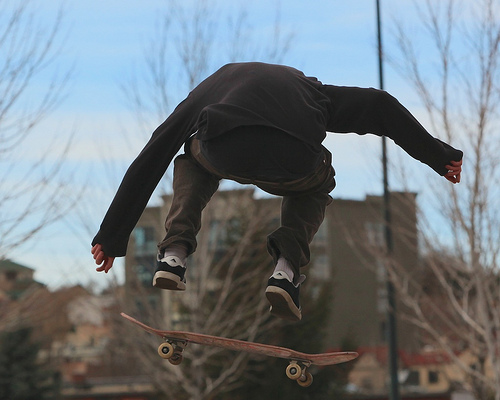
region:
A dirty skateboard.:
[118, 311, 360, 384]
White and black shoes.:
[150, 255, 308, 322]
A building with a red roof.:
[358, 341, 451, 397]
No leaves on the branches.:
[364, 213, 499, 334]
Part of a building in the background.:
[337, 190, 417, 334]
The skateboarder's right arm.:
[331, 82, 465, 182]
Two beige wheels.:
[155, 343, 186, 365]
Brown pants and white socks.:
[159, 158, 336, 275]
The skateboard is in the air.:
[119, 310, 360, 386]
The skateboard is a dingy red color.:
[119, 312, 357, 387]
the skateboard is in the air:
[107, 297, 352, 391]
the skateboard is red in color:
[101, 310, 393, 376]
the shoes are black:
[145, 253, 332, 325]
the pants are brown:
[161, 179, 332, 256]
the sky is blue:
[62, 13, 470, 63]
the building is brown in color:
[122, 206, 429, 331]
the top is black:
[173, 67, 422, 129]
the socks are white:
[156, 243, 303, 282]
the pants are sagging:
[169, 121, 360, 211]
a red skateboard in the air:
[120, 303, 357, 386]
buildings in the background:
[9, 195, 496, 398]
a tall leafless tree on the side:
[368, 10, 498, 398]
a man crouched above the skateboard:
[92, 62, 464, 299]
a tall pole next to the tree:
[366, 2, 428, 397]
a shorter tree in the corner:
[8, 322, 75, 398]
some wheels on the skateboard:
[280, 362, 313, 385]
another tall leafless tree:
[1, 0, 84, 271]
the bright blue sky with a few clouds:
[6, 3, 497, 93]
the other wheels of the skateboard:
[149, 338, 184, 363]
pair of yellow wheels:
[152, 341, 186, 368]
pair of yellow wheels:
[282, 364, 319, 387]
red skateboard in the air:
[110, 302, 372, 399]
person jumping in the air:
[69, 20, 476, 398]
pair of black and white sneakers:
[147, 252, 317, 324]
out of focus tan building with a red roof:
[335, 337, 455, 399]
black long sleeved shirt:
[87, 33, 462, 262]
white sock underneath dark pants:
[164, 241, 191, 265]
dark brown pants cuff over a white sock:
[253, 222, 317, 276]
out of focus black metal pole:
[360, 1, 420, 398]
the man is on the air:
[21, 32, 436, 398]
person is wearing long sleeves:
[66, 37, 480, 242]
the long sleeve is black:
[78, 44, 495, 323]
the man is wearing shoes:
[105, 259, 392, 337]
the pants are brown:
[157, 144, 363, 293]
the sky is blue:
[72, 42, 124, 99]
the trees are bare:
[11, 40, 114, 294]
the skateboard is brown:
[116, 296, 374, 398]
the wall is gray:
[333, 260, 370, 335]